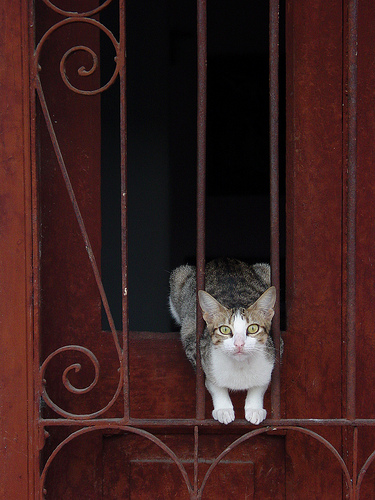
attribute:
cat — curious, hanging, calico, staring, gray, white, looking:
[167, 256, 284, 424]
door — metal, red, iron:
[0, 1, 374, 500]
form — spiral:
[32, 17, 117, 96]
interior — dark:
[102, 0, 284, 335]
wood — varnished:
[37, 4, 374, 500]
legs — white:
[205, 384, 269, 424]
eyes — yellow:
[217, 323, 260, 337]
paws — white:
[212, 408, 268, 424]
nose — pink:
[233, 339, 244, 349]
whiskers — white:
[204, 342, 278, 361]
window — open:
[96, 4, 283, 335]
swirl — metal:
[39, 345, 121, 420]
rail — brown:
[40, 418, 374, 427]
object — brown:
[40, 424, 196, 489]